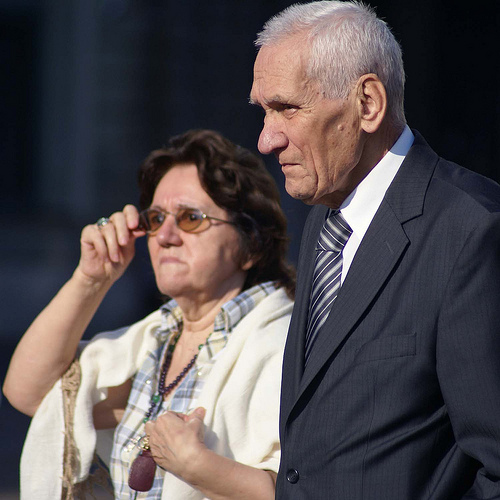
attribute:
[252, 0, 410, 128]
hair — white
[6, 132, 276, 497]
woman — elderly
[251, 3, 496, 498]
man — elderly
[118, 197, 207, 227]
glasses — dark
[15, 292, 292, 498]
coat — white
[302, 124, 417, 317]
shirt — white 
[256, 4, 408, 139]
hair — white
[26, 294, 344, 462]
shawl — white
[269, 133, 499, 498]
blazer — dark 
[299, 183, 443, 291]
shirt — white 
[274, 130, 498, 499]
coat — grey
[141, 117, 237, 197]
hair — dark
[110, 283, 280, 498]
shirt — blue and white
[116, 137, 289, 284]
hair — brown